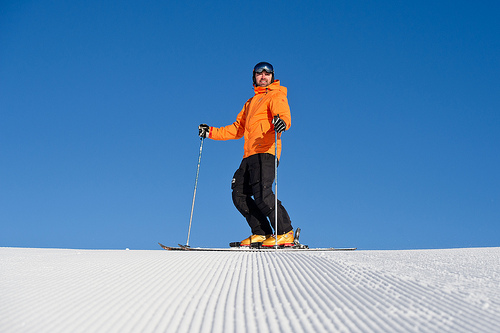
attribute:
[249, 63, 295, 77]
goggles — black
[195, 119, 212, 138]
gloves — black, white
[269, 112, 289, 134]
gloves — black, white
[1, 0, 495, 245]
sky — blue, clear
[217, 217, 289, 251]
boots — orange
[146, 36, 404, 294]
person — skiing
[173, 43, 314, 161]
jacket — orange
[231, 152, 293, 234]
ski pants — black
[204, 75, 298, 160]
jacket — orange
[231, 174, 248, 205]
knee — slightly bent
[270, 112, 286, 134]
glove — black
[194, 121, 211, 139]
glove — black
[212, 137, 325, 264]
pants — black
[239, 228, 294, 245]
shoes — orange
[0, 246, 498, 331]
snow — white, raked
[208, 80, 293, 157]
ski coat — orange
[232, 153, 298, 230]
pants — black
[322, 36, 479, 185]
sky — bright, blue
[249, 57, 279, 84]
hat — black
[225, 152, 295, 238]
pants — black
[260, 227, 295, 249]
shoe — brown, ski shoe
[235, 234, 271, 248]
shoe — brown, ski shoe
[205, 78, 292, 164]
jacket — orange